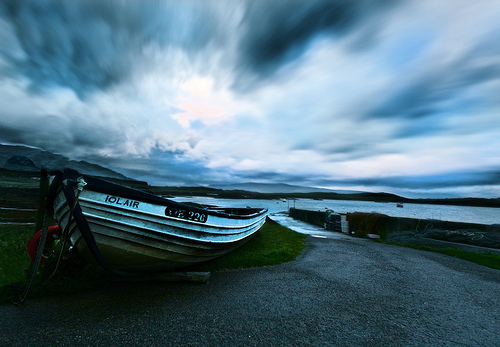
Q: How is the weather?
A: It is overcast.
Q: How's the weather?
A: It is overcast.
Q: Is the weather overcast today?
A: Yes, it is overcast.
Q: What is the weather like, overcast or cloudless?
A: It is overcast.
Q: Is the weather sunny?
A: No, it is overcast.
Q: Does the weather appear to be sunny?
A: No, it is overcast.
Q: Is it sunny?
A: No, it is overcast.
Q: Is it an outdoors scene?
A: Yes, it is outdoors.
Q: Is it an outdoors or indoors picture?
A: It is outdoors.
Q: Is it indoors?
A: No, it is outdoors.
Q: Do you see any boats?
A: Yes, there is a boat.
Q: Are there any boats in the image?
A: Yes, there is a boat.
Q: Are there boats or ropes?
A: Yes, there is a boat.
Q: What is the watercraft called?
A: The watercraft is a boat.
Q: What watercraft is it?
A: The watercraft is a boat.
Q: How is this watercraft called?
A: This is a boat.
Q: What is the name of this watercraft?
A: This is a boat.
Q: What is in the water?
A: The boat is in the water.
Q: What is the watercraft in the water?
A: The watercraft is a boat.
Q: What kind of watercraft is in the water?
A: The watercraft is a boat.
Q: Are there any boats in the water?
A: Yes, there is a boat in the water.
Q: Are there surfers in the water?
A: No, there is a boat in the water.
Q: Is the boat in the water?
A: Yes, the boat is in the water.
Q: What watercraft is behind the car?
A: The watercraft is a boat.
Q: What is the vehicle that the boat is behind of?
A: The vehicle is a car.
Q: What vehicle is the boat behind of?
A: The boat is behind the car.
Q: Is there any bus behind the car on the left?
A: No, there is a boat behind the car.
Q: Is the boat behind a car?
A: Yes, the boat is behind a car.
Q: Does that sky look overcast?
A: Yes, the sky is overcast.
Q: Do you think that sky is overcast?
A: Yes, the sky is overcast.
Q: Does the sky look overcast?
A: Yes, the sky is overcast.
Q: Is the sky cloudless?
A: No, the sky is overcast.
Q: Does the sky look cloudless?
A: No, the sky is overcast.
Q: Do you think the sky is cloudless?
A: No, the sky is overcast.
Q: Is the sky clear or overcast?
A: The sky is overcast.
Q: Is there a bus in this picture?
A: No, there are no buses.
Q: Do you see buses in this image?
A: No, there are no buses.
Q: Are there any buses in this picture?
A: No, there are no buses.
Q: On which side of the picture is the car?
A: The car is on the left of the image.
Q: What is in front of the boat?
A: The car is in front of the boat.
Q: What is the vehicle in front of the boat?
A: The vehicle is a car.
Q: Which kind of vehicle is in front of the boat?
A: The vehicle is a car.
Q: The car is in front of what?
A: The car is in front of the boat.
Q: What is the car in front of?
A: The car is in front of the boat.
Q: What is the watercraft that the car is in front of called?
A: The watercraft is a boat.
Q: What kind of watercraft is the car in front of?
A: The car is in front of the boat.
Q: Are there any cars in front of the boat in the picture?
A: Yes, there is a car in front of the boat.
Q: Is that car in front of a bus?
A: No, the car is in front of the boat.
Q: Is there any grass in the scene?
A: Yes, there is grass.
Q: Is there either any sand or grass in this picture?
A: Yes, there is grass.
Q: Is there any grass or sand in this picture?
A: Yes, there is grass.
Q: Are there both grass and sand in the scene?
A: No, there is grass but no sand.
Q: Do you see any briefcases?
A: No, there are no briefcases.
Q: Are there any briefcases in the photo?
A: No, there are no briefcases.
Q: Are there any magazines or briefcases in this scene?
A: No, there are no briefcases or magazines.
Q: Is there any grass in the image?
A: Yes, there is grass.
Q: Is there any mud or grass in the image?
A: Yes, there is grass.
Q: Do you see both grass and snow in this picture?
A: No, there is grass but no snow.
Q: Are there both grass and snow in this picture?
A: No, there is grass but no snow.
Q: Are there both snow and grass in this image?
A: No, there is grass but no snow.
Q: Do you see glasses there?
A: No, there are no glasses.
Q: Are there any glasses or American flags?
A: No, there are no glasses or American flags.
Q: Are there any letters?
A: Yes, there are letters.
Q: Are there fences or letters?
A: Yes, there are letters.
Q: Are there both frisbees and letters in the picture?
A: No, there are letters but no frisbees.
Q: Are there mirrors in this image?
A: No, there are no mirrors.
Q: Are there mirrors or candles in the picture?
A: No, there are no mirrors or candles.